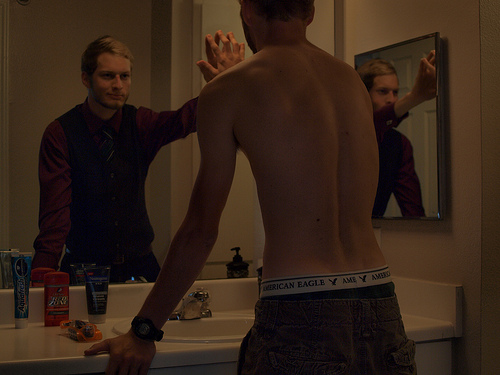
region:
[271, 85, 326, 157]
the guy is shirtless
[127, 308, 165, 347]
he is wearing a watch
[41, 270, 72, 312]
the container is red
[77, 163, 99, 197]
the vest is black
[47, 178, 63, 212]
the shirt is maroon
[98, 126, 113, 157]
the tie is striped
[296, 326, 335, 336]
the pants are brown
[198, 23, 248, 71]
the guy is touching the mirorr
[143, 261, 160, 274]
the pants are black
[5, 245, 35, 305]
the tube is blue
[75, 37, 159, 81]
man has blond hair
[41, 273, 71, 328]
red container of deodorant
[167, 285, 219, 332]
chrome faucet on sink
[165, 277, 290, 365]
sink is white and porcelain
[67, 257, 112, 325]
blue container of hair product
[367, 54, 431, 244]
mirror to right of man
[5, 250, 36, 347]
blue bottle of toothpaste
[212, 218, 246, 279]
bottle for soap dispensing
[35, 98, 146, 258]
man wears blue vest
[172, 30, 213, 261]
white door behind man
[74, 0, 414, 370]
the man looks in the mirror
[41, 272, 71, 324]
deodorant is on counter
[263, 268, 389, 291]
he is wearing american eagle underwear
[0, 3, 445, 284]
two mirrors in bathroom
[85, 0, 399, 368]
man is not wearing a shirt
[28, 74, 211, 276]
man is wearing a shirt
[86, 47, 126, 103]
man is looking at himself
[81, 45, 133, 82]
man has short hiar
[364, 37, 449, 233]
a small mirror on the right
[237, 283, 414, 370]
the man wears pants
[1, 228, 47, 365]
The toothpaste is standing upright.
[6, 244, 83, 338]
The roll on deoderant is next to the toothpaste.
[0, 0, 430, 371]
The man is looking at someone.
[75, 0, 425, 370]
The man is shirtless.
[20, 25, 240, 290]
The man is dressed.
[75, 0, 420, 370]
The man is wearing a watch.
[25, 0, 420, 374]
The men's hands are touching.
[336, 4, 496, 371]
The mirror is on the right side wall.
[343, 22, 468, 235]
The mirror is rectangular.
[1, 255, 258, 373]
A razor is sitting on the bathroom counter.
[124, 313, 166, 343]
a black large wrist watch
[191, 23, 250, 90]
the man's hand on the mirror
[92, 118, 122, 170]
part of a tie around the man's neck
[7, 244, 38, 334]
a large tube of toothpaste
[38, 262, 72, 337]
a red tube of deodorant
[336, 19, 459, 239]
a medicine cabinet on the wall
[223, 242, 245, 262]
the pump of a bottle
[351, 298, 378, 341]
a belt loop on the clothing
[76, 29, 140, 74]
the hair on the young man's head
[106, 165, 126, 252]
a row of buttons on the vest